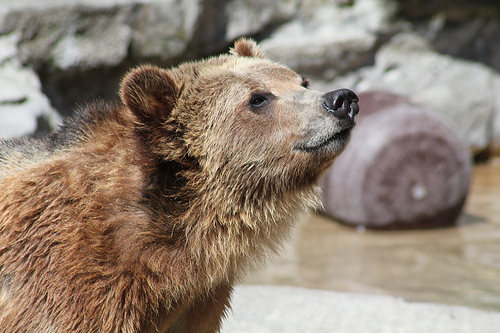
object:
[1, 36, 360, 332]
bear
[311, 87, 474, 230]
barrel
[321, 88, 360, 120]
nose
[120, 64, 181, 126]
right ear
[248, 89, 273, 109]
eye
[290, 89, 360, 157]
muzzle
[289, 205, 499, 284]
water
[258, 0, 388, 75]
rock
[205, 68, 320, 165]
face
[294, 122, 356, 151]
mouth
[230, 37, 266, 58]
ear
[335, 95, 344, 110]
nostril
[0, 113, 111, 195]
fur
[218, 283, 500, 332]
ground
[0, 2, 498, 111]
background